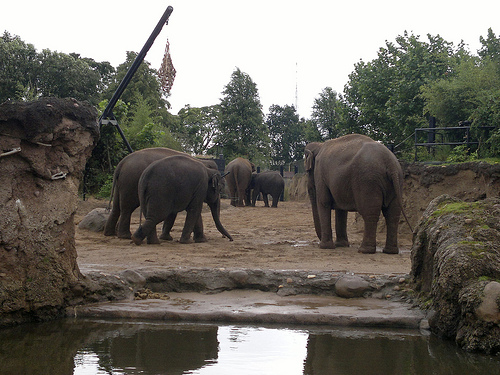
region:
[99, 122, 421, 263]
five elephants in a pen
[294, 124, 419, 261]
a big elephant is alone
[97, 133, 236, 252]
two elephants are together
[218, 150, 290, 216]
two elephants are together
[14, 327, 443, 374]
reflections on water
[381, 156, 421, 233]
tail of elephant is long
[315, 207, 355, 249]
front feet of elephant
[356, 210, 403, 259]
back feet of elephant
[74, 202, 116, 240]
a stone on side of elephant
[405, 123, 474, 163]
a fence on side of pen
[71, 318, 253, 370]
shadow of house on water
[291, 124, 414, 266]
one brown elephant on dirt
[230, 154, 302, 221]
two elephants standing beside eachother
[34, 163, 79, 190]
white stuff in the mudd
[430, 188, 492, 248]
green grass on brown dirt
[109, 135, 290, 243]
four elephants in a row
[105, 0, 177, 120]
black stick sticking out mud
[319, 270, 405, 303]
one brown rock in mud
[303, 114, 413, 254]
elephant facing the wrong way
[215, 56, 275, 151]
green tree facing the camera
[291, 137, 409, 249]
elephant standing in enclosure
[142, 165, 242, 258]
elephant standing in enclosure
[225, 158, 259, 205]
elephant standing in enclosure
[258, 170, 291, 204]
elephant standing in enclosure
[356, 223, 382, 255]
foot of the elephant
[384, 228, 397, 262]
foot of the elephant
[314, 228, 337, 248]
foot of the elephant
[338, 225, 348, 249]
foot of the elephant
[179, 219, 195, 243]
foot of the elephant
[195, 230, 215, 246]
foot of the elephant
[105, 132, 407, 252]
elephants walking on the mud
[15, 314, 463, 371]
water in the elephant area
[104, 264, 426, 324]
steps leading to the water in the elephant area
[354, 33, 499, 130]
trees in the background to the elephant area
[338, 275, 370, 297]
big rock on the step to the elephant area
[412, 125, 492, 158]
black gate on the top of the elephant area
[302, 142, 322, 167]
head of one elephant in the elephant area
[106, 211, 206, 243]
feet of two elephant walking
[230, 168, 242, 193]
long tail of elaephant in front of other elepahants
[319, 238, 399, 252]
bottom feet of one elephant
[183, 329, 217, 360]
the brown pond in front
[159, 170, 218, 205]
the baby elephant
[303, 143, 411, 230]
the big grey elephant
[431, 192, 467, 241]
the rock on the side of the picture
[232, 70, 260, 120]
the green trees in the distance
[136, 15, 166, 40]
a black pole in the distance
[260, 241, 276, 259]
the muddy brown ground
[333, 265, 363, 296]
the grey rocks on the shore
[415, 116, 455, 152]
a black fence in the distance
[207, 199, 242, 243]
the elephant's tusk